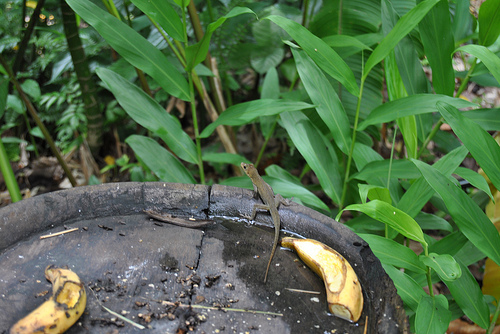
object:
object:
[142, 206, 211, 229]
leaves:
[335, 197, 427, 246]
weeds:
[332, 198, 464, 332]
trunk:
[53, 0, 107, 166]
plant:
[53, 0, 113, 167]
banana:
[278, 234, 366, 323]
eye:
[241, 165, 247, 170]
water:
[200, 214, 376, 333]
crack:
[180, 182, 218, 333]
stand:
[54, 203, 292, 333]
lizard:
[233, 160, 298, 285]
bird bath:
[0, 178, 413, 333]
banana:
[0, 264, 89, 333]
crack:
[179, 190, 207, 313]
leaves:
[355, 90, 480, 133]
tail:
[265, 221, 283, 285]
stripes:
[73, 55, 87, 66]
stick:
[37, 223, 84, 241]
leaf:
[94, 65, 201, 163]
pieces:
[122, 268, 235, 331]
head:
[238, 160, 261, 178]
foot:
[284, 196, 295, 206]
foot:
[238, 211, 253, 221]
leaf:
[405, 151, 500, 267]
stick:
[282, 282, 320, 294]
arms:
[251, 184, 259, 200]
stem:
[280, 235, 298, 249]